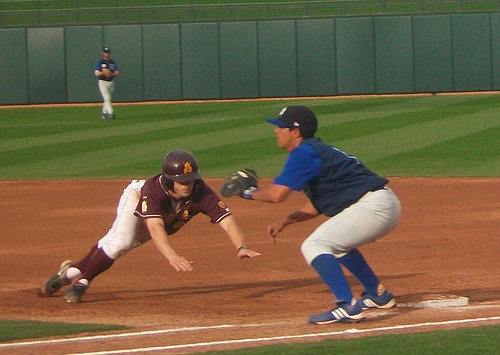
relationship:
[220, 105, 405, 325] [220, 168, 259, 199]
baseball player holding glove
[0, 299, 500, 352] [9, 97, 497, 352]
chalk line on field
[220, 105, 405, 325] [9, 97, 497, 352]
baseball player on field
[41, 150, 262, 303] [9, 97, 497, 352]
man on field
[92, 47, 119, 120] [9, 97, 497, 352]
player on field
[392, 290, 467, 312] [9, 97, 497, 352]
base on field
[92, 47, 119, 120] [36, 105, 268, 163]
player in outfield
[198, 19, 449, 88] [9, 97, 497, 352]
green fence behind field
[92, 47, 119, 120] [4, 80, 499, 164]
player in outfield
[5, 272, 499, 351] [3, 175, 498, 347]
chalk line on dirt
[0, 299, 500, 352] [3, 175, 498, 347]
chalk line on dirt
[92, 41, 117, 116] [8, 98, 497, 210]
player in outfield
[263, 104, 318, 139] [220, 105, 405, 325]
baseball cap on baseball player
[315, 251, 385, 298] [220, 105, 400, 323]
blue socks on man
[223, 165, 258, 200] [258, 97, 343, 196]
glove on baseball player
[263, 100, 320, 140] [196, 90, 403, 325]
baseball cap on player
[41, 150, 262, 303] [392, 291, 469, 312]
man reaching for base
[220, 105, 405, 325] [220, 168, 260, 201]
baseball player has glove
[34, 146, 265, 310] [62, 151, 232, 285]
man in uniform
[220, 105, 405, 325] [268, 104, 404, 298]
baseball player in uniform